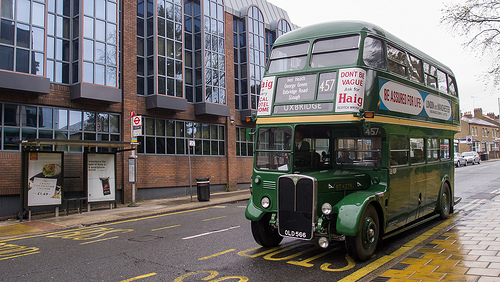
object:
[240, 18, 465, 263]
bus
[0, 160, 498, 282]
street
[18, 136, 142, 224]
bus stop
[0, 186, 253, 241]
sidewalk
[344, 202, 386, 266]
wheel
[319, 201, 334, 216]
headlight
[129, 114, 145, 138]
sign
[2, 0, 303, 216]
building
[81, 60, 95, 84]
window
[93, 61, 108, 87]
window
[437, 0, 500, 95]
tree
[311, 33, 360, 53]
window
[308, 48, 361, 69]
window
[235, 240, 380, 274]
word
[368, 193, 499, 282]
sidewalk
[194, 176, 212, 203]
trash can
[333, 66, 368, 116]
advertisement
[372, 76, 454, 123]
advertisement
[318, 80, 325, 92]
number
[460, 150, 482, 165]
car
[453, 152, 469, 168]
car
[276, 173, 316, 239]
grill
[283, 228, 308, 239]
number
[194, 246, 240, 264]
line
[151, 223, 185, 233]
line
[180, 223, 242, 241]
line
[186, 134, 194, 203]
pole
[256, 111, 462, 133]
stripe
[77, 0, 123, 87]
reflection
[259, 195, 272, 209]
headlight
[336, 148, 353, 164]
passenger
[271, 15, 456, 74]
roof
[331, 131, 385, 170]
windshield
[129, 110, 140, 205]
pole